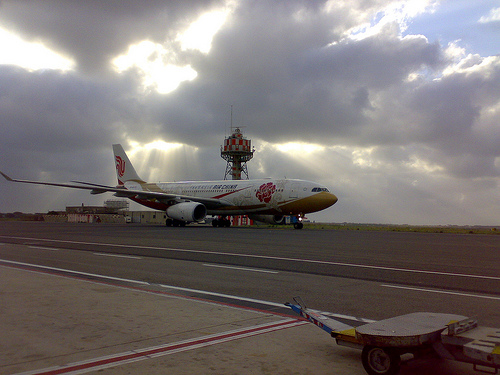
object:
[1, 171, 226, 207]
wing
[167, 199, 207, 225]
engine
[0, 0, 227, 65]
cloud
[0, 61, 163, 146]
cloud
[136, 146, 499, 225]
cloud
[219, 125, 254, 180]
tower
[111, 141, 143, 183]
tail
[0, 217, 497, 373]
runway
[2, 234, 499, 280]
strip marking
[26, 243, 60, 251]
strip marking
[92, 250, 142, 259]
strip marking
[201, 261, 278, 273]
strip marking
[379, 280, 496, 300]
strip marking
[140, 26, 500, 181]
clouds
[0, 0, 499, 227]
sky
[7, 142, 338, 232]
airplane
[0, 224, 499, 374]
ground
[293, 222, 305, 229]
front wheel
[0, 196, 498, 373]
airfield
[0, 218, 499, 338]
grey tarmac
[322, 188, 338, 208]
nose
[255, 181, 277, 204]
brand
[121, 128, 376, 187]
light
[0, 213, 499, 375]
tarmark